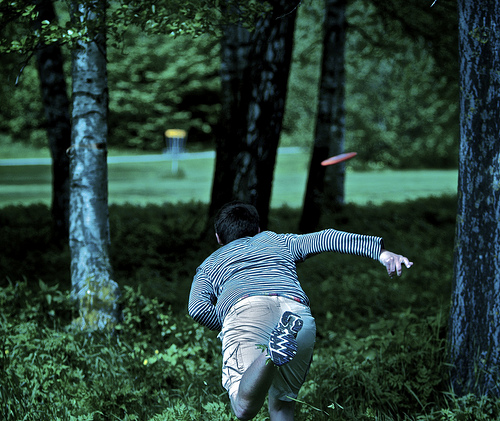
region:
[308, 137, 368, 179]
frisbee in the sky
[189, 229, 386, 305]
Man wearing a stripped shirt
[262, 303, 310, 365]
man wearing sneakers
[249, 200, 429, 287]
man throwing a frisbee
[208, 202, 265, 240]
man with black hair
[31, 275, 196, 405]
leaves on the ground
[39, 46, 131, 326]
tree growing in the park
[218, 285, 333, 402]
man wearing khaki shorts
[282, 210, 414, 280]
man with his arms out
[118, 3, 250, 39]
leaves hanging from a tree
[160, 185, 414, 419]
the person is running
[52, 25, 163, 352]
the bark of a tree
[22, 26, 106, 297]
the bark of a tree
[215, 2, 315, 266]
the bark of a tree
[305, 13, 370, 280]
the bark of a tree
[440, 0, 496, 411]
the bark of a tree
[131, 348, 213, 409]
these are plants on the ground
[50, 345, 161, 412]
these are plants on the ground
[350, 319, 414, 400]
these are plants on the ground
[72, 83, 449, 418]
a man playing freesbee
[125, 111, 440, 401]
a man running after freesbee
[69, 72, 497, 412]
a man catching a freesbee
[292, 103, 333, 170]
a freesbee in the air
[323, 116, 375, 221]
a freesbee flying in the air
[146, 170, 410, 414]
a man wearing a long sleeve shirt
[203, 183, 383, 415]
a man wearing shorts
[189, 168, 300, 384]
a man with short hair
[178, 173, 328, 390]
a man with black hair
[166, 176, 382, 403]
PErson in the field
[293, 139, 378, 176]
Red frisbee in the air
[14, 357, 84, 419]
Patch of green grass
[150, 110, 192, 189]
Disc gulf in the field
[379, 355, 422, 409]
Patch of green grass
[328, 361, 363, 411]
Patch of green grass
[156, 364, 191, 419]
Patch of green grass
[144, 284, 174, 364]
Patch of green grass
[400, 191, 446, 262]
Patch of green grass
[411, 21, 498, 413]
Trunk of large tree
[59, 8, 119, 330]
a trunk of a tree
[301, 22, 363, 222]
a trunk of a tree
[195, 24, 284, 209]
the trunks of two trees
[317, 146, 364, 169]
an orange frisbee in the air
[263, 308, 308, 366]
the bottom of a shoe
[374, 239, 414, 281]
a hand of a person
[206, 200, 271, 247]
the head of a person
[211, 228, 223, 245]
the ear of a person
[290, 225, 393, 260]
the arm of a person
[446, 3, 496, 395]
the trunk of a tree